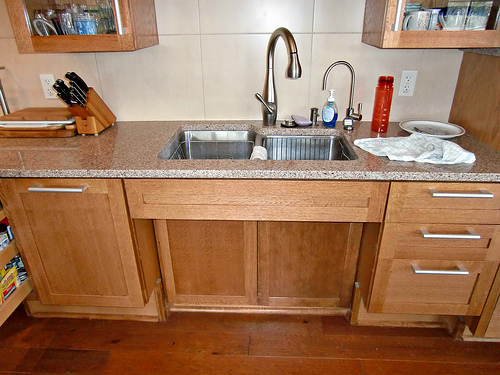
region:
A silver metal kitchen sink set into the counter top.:
[155, 125, 359, 162]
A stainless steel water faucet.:
[252, 26, 302, 128]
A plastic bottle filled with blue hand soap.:
[320, 87, 338, 126]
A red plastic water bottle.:
[370, 75, 395, 134]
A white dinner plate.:
[398, 119, 465, 139]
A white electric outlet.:
[395, 68, 417, 97]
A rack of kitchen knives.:
[52, 70, 117, 136]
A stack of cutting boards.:
[0, 105, 74, 137]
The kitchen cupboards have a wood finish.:
[0, 178, 499, 341]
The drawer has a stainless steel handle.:
[426, 186, 495, 201]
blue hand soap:
[322, 88, 337, 126]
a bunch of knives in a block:
[52, 71, 116, 136]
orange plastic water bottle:
[370, 75, 393, 135]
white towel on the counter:
[352, 134, 473, 166]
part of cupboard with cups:
[360, 0, 495, 45]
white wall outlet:
[37, 73, 56, 97]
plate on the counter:
[399, 118, 465, 139]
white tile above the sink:
[2, 2, 462, 124]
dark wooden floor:
[0, 303, 498, 371]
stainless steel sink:
[156, 128, 258, 160]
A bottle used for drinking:
[370, 74, 393, 130]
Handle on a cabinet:
[24, 183, 87, 192]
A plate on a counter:
[399, 119, 465, 139]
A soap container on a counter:
[322, 89, 338, 128]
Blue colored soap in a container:
[321, 90, 340, 127]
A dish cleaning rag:
[353, 132, 475, 165]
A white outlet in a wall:
[40, 74, 58, 98]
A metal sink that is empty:
[260, 132, 355, 162]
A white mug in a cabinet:
[403, 8, 429, 30]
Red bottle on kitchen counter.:
[372, 69, 395, 133]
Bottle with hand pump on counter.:
[320, 83, 338, 128]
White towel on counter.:
[352, 124, 477, 172]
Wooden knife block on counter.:
[67, 88, 115, 137]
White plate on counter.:
[398, 109, 470, 141]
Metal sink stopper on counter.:
[280, 113, 299, 130]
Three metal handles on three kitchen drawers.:
[405, 183, 492, 286]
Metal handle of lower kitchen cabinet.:
[19, 180, 91, 203]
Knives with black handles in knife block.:
[48, 69, 89, 104]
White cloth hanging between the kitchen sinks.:
[245, 140, 269, 162]